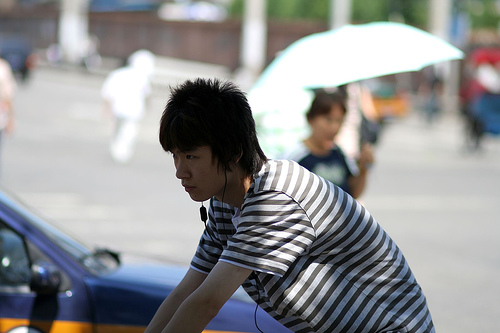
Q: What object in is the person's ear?
A: Headphones.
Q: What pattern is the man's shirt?
A: Striped.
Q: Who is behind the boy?
A: A person holding an umbrella.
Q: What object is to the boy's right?
A: Car.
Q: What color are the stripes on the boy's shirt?
A: Grey and white.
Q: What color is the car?
A: Blue and yellow.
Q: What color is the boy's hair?
A: Black.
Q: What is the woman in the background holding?
A: Umbrella.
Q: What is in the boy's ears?
A: Ear buds.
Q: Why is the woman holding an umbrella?
A: Protection from the sun's rays.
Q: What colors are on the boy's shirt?
A: Black and white.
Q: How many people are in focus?
A: 1.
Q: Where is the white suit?
A: On a person in the background.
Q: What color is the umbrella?
A: White.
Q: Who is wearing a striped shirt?
A: Man in foreground.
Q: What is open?
A: An umbrella.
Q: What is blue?
A: Car.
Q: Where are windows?
A: On the car.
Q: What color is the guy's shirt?
A: Gray and white.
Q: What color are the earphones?
A: Black.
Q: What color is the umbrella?
A: White.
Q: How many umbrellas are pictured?
A: One.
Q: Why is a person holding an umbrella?
A: To block the sun.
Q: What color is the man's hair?
A: Black.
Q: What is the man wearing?
A: A t-shirt.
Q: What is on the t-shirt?
A: Stripes.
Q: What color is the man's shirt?
A: Black and white.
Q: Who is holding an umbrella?
A: A woman.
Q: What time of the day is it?
A: Daytime.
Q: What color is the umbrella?
A: White.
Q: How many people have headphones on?
A: One.